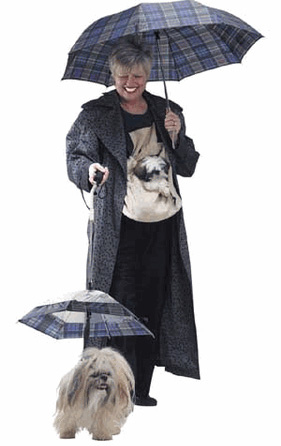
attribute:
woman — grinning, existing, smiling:
[61, 44, 200, 413]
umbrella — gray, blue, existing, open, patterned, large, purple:
[57, 2, 267, 134]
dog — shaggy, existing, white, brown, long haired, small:
[51, 343, 136, 445]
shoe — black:
[133, 394, 159, 407]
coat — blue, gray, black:
[62, 88, 202, 384]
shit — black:
[120, 104, 185, 228]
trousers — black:
[108, 217, 178, 402]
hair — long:
[48, 345, 137, 438]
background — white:
[4, 1, 278, 445]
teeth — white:
[118, 85, 140, 93]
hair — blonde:
[100, 39, 157, 78]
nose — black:
[99, 373, 111, 385]